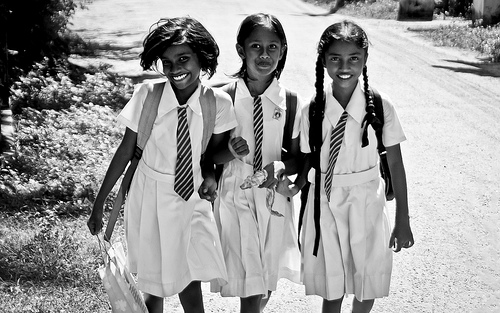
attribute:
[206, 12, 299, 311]
person — standing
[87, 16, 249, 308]
person — standing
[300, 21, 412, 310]
person — standing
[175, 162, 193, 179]
stripe — white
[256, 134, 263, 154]
stripe — white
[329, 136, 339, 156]
stripe — white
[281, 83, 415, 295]
school uniform — white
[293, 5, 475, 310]
child — smiling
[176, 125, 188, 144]
stripe — white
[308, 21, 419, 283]
child — smiling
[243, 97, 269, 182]
tie — worn